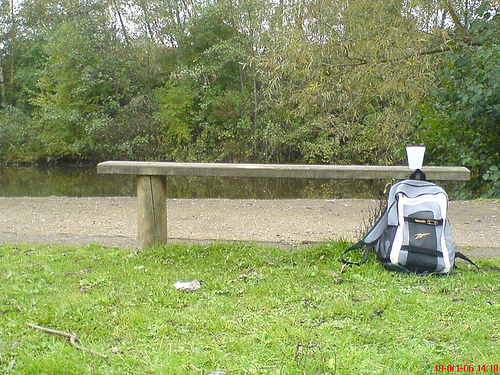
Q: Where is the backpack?
A: Leaning on the bench.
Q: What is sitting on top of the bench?
A: Cup.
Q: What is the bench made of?
A: Wood.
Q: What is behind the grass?
A: Empty park bench.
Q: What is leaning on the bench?
A: Backpack.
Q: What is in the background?
A: Lots of green trees and shrubbery.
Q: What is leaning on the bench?
A: A gray and white backpack.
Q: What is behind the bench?
A: A dirt walking path.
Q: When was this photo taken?
A: On a bright day.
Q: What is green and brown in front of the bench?
A: Grass.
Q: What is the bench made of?
A: Wood.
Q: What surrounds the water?
A: Trees.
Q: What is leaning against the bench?
A: Backpack.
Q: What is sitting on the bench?
A: Cup.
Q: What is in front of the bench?
A: Grass.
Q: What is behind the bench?
A: Sidewalk.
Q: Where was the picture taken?
A: Park.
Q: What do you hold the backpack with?
A: Strap.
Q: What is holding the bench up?
A: Log.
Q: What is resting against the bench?
A: A backpack.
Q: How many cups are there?
A: One.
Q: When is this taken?
A: Daytime.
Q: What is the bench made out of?
A: Wood.